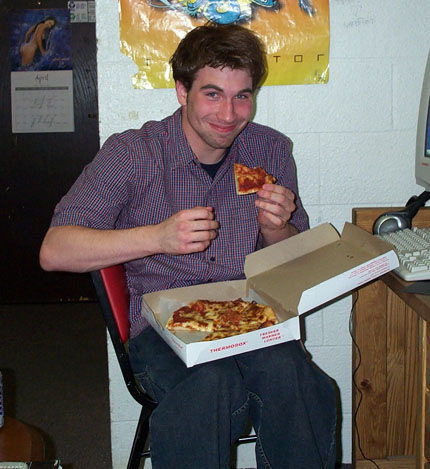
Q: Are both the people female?
A: No, they are both male and female.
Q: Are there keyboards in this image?
A: Yes, there is a keyboard.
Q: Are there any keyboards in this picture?
A: Yes, there is a keyboard.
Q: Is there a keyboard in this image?
A: Yes, there is a keyboard.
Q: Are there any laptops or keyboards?
A: Yes, there is a keyboard.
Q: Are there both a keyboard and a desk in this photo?
A: Yes, there are both a keyboard and a desk.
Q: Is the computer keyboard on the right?
A: Yes, the keyboard is on the right of the image.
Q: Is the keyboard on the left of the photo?
A: No, the keyboard is on the right of the image.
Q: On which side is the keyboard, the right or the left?
A: The keyboard is on the right of the image.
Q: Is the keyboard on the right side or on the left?
A: The keyboard is on the right of the image.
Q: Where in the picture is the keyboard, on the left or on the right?
A: The keyboard is on the right of the image.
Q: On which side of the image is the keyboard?
A: The keyboard is on the right of the image.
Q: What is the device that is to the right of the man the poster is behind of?
A: The device is a keyboard.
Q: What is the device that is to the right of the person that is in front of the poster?
A: The device is a keyboard.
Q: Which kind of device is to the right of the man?
A: The device is a keyboard.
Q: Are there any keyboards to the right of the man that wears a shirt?
A: Yes, there is a keyboard to the right of the man.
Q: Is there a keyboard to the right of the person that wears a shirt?
A: Yes, there is a keyboard to the right of the man.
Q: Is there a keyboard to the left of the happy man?
A: No, the keyboard is to the right of the man.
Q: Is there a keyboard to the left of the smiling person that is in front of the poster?
A: No, the keyboard is to the right of the man.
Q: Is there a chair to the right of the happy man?
A: No, there is a keyboard to the right of the man.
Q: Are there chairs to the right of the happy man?
A: No, there is a keyboard to the right of the man.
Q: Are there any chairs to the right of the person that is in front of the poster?
A: No, there is a keyboard to the right of the man.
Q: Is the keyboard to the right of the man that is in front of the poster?
A: Yes, the keyboard is to the right of the man.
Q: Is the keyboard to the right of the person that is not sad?
A: Yes, the keyboard is to the right of the man.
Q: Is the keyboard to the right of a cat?
A: No, the keyboard is to the right of the man.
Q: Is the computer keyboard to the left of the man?
A: No, the keyboard is to the right of the man.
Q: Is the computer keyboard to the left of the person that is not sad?
A: No, the keyboard is to the right of the man.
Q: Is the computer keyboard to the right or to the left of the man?
A: The keyboard is to the right of the man.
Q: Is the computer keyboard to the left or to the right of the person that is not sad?
A: The keyboard is to the right of the man.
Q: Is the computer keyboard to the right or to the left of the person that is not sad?
A: The keyboard is to the right of the man.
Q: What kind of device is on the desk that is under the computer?
A: The device is a keyboard.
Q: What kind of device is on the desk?
A: The device is a keyboard.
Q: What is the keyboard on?
A: The keyboard is on the desk.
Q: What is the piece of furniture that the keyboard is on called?
A: The piece of furniture is a desk.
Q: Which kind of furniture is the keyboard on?
A: The keyboard is on the desk.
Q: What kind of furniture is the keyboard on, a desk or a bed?
A: The keyboard is on a desk.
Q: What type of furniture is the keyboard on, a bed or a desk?
A: The keyboard is on a desk.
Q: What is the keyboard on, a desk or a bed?
A: The keyboard is on a desk.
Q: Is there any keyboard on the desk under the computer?
A: Yes, there is a keyboard on the desk.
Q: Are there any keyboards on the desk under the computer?
A: Yes, there is a keyboard on the desk.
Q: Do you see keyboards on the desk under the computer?
A: Yes, there is a keyboard on the desk.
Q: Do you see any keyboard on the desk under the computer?
A: Yes, there is a keyboard on the desk.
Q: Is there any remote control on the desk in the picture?
A: No, there is a keyboard on the desk.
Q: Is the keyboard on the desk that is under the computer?
A: Yes, the keyboard is on the desk.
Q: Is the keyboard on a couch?
A: No, the keyboard is on the desk.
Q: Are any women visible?
A: Yes, there is a woman.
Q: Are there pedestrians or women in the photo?
A: Yes, there is a woman.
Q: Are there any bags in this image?
A: No, there are no bags.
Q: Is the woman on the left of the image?
A: Yes, the woman is on the left of the image.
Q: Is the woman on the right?
A: No, the woman is on the left of the image.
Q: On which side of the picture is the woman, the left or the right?
A: The woman is on the left of the image.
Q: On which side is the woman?
A: The woman is on the left of the image.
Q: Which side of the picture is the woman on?
A: The woman is on the left of the image.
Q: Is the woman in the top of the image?
A: Yes, the woman is in the top of the image.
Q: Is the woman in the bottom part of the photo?
A: No, the woman is in the top of the image.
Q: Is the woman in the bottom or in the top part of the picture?
A: The woman is in the top of the image.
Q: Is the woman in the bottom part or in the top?
A: The woman is in the top of the image.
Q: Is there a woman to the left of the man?
A: Yes, there is a woman to the left of the man.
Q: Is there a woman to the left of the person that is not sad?
A: Yes, there is a woman to the left of the man.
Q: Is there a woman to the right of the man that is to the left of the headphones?
A: No, the woman is to the left of the man.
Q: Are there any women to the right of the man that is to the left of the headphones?
A: No, the woman is to the left of the man.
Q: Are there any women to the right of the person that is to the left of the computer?
A: No, the woman is to the left of the man.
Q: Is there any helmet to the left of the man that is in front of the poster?
A: No, there is a woman to the left of the man.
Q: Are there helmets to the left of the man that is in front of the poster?
A: No, there is a woman to the left of the man.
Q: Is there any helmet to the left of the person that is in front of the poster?
A: No, there is a woman to the left of the man.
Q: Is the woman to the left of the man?
A: Yes, the woman is to the left of the man.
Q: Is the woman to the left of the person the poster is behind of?
A: Yes, the woman is to the left of the man.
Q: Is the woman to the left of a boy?
A: No, the woman is to the left of the man.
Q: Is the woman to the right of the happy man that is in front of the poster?
A: No, the woman is to the left of the man.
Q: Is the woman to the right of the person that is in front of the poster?
A: No, the woman is to the left of the man.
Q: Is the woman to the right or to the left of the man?
A: The woman is to the left of the man.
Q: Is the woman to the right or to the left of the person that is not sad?
A: The woman is to the left of the man.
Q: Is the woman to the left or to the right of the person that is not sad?
A: The woman is to the left of the man.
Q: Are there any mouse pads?
A: No, there are no mouse pads.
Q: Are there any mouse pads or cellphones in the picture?
A: No, there are no mouse pads or cellphones.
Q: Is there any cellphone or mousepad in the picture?
A: No, there are no mouse pads or cell phones.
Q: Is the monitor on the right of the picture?
A: Yes, the monitor is on the right of the image.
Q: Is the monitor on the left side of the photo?
A: No, the monitor is on the right of the image.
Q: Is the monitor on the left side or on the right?
A: The monitor is on the right of the image.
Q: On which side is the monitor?
A: The monitor is on the right of the image.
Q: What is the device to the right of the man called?
A: The device is a monitor.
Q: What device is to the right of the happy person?
A: The device is a monitor.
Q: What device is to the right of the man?
A: The device is a monitor.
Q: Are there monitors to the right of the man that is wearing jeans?
A: Yes, there is a monitor to the right of the man.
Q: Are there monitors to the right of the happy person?
A: Yes, there is a monitor to the right of the man.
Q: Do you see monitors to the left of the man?
A: No, the monitor is to the right of the man.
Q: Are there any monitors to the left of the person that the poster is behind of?
A: No, the monitor is to the right of the man.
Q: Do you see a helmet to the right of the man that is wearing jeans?
A: No, there is a monitor to the right of the man.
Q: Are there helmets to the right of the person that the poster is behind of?
A: No, there is a monitor to the right of the man.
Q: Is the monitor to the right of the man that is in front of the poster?
A: Yes, the monitor is to the right of the man.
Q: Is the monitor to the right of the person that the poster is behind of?
A: Yes, the monitor is to the right of the man.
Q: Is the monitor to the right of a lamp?
A: No, the monitor is to the right of the man.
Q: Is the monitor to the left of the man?
A: No, the monitor is to the right of the man.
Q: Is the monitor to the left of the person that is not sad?
A: No, the monitor is to the right of the man.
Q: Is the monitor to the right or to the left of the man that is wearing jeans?
A: The monitor is to the right of the man.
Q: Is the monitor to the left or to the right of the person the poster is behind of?
A: The monitor is to the right of the man.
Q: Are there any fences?
A: No, there are no fences.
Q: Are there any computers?
A: Yes, there is a computer.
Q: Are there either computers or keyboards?
A: Yes, there is a computer.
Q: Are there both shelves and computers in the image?
A: No, there is a computer but no shelves.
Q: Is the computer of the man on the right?
A: Yes, the computer is on the right of the image.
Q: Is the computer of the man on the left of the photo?
A: No, the computer is on the right of the image.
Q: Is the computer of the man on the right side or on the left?
A: The computer is on the right of the image.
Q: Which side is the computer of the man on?
A: The computer is on the right of the image.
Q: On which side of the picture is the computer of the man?
A: The computer is on the right of the image.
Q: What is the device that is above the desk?
A: The device is a computer.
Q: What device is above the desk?
A: The device is a computer.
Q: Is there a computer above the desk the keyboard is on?
A: Yes, there is a computer above the desk.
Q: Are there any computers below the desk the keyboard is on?
A: No, the computer is above the desk.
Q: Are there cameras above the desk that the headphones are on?
A: No, there is a computer above the desk.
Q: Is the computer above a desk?
A: Yes, the computer is above a desk.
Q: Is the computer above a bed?
A: No, the computer is above a desk.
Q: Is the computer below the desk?
A: No, the computer is above the desk.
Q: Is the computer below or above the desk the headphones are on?
A: The computer is above the desk.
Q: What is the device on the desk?
A: The device is a computer.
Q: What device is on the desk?
A: The device is a computer.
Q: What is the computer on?
A: The computer is on the desk.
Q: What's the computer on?
A: The computer is on the desk.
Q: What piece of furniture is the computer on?
A: The computer is on the desk.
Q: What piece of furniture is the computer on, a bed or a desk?
A: The computer is on a desk.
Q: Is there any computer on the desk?
A: Yes, there is a computer on the desk.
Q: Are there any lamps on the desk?
A: No, there is a computer on the desk.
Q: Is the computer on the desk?
A: Yes, the computer is on the desk.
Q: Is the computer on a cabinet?
A: No, the computer is on the desk.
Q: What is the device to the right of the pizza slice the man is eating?
A: The device is a computer.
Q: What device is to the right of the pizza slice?
A: The device is a computer.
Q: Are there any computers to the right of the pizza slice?
A: Yes, there is a computer to the right of the pizza slice.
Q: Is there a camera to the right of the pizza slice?
A: No, there is a computer to the right of the pizza slice.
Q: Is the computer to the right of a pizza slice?
A: Yes, the computer is to the right of a pizza slice.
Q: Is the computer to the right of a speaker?
A: No, the computer is to the right of a pizza slice.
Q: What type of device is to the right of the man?
A: The device is a computer.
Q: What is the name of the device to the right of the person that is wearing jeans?
A: The device is a computer.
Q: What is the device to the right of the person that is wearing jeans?
A: The device is a computer.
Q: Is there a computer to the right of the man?
A: Yes, there is a computer to the right of the man.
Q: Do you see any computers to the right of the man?
A: Yes, there is a computer to the right of the man.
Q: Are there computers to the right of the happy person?
A: Yes, there is a computer to the right of the man.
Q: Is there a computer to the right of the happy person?
A: Yes, there is a computer to the right of the man.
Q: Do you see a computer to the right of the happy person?
A: Yes, there is a computer to the right of the man.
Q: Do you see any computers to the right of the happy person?
A: Yes, there is a computer to the right of the man.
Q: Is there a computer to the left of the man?
A: No, the computer is to the right of the man.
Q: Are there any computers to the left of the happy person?
A: No, the computer is to the right of the man.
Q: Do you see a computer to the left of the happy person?
A: No, the computer is to the right of the man.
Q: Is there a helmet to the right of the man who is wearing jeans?
A: No, there is a computer to the right of the man.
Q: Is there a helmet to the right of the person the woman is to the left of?
A: No, there is a computer to the right of the man.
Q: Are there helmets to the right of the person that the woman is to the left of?
A: No, there is a computer to the right of the man.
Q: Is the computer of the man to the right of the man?
A: Yes, the computer is to the right of the man.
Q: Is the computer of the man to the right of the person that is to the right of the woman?
A: Yes, the computer is to the right of the man.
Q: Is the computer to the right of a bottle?
A: No, the computer is to the right of the man.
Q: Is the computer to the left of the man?
A: No, the computer is to the right of the man.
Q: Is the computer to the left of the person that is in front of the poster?
A: No, the computer is to the right of the man.